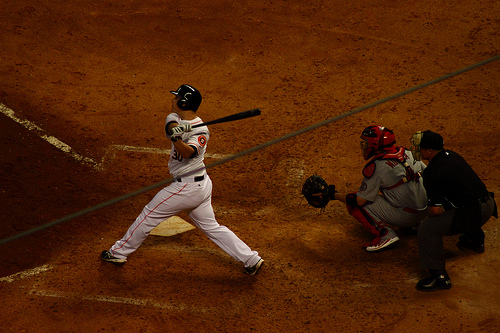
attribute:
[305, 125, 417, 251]
catcher's — wearing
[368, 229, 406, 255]
shoe — white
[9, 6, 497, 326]
ground — for playing, bare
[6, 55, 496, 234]
wire — grey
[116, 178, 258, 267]
uniform pants — white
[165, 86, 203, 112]
helmet — black, dark blue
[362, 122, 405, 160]
helmet — colored, red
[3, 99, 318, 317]
lines — covered, white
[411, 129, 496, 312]
umpire — crouching, wearing black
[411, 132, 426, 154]
mask — white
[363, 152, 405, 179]
chest guard — red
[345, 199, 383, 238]
shin pads — red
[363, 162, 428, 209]
shirt — grey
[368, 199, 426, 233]
pants — grey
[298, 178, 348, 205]
glove — extended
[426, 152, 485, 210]
t shirt — black, colored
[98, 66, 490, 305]
baseball club — a team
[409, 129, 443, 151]
hat — black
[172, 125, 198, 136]
glove — white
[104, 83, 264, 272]
man — swinging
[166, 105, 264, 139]
baseball bat — black